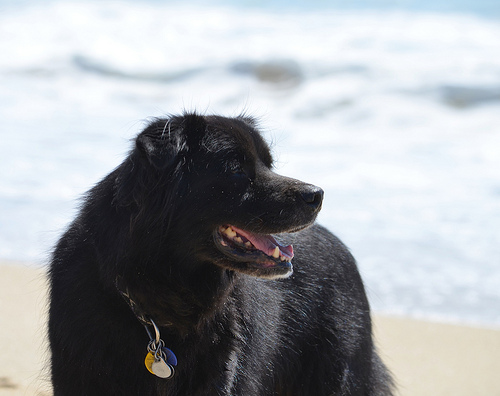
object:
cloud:
[0, 0, 79, 127]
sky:
[240, 0, 500, 19]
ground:
[0, 259, 499, 396]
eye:
[220, 161, 243, 178]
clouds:
[406, 0, 499, 139]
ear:
[131, 117, 193, 173]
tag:
[148, 353, 177, 380]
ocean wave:
[0, 49, 499, 118]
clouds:
[43, 16, 243, 71]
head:
[128, 106, 325, 284]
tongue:
[227, 225, 291, 261]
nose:
[295, 184, 325, 209]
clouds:
[309, 0, 499, 154]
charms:
[160, 347, 177, 367]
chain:
[112, 273, 176, 330]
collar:
[112, 272, 182, 379]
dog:
[39, 97, 398, 395]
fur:
[258, 291, 340, 360]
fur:
[144, 227, 187, 308]